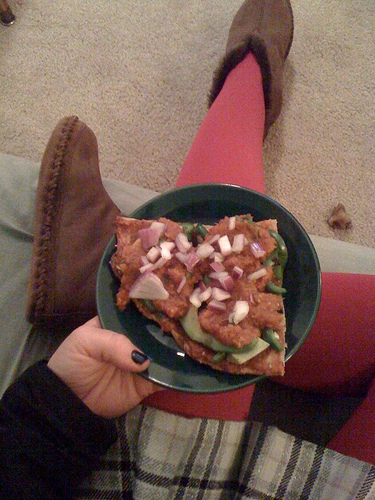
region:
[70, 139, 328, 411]
a plate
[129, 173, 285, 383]
a plate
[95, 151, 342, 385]
a slice of bread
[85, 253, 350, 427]
onions and peppers on bread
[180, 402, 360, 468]
a plaid skirt on woman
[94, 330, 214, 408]
the nail is painted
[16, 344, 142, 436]
the sleeve is black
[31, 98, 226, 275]
the carpet is tan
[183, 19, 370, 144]
the leggings are red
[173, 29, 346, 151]
the boots are brown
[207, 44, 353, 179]
boots have fuzzy trim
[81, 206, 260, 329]
the plate is green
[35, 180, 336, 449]
a woman holding a plate of food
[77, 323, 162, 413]
a woman with painted finger nail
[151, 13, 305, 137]
a woman wearing brown shoes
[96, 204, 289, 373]
two slices of pizza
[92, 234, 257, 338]
chopped onions on a pizza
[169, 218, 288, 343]
chopped grenn peppers on a pizza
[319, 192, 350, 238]
a fake nose on the floor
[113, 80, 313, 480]
a woman wearing red leggins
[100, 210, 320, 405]
a green plate with pizza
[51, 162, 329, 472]
a woman holding a plate of pizza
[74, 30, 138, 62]
carpet on the floor.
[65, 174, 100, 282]
brown slipper on woman's foot.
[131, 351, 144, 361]
black fingernail polish on fingernail.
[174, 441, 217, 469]
pattern on couch material.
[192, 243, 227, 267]
onions on top of food.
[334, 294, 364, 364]
red tights on woman's leg.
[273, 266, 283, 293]
green peppers on food.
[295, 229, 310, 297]
green plate in woman's hand.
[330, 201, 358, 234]
item on the floor.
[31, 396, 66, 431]
black sleeve on woman's sweater.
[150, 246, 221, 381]
A slice of pizza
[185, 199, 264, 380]
A slice of pizza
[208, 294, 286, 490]
A slice of pizza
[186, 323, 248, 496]
A slice of pizza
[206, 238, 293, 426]
A slice of pizza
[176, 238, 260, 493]
A slice of pizza